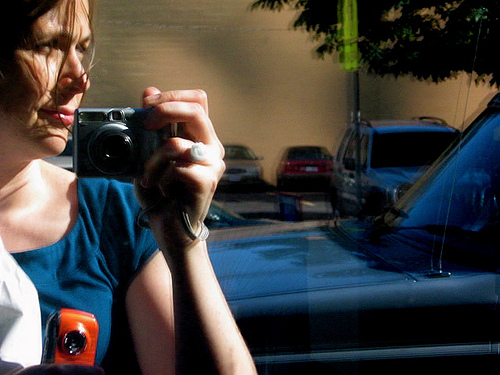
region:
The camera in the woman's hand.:
[74, 109, 189, 184]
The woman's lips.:
[38, 106, 71, 126]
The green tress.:
[260, 3, 498, 95]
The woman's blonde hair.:
[4, 0, 45, 137]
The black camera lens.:
[101, 136, 138, 162]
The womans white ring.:
[186, 143, 208, 163]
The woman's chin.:
[27, 129, 69, 160]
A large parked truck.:
[346, 115, 456, 228]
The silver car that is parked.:
[213, 137, 263, 188]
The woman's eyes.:
[37, 33, 94, 60]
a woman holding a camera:
[32, 61, 269, 314]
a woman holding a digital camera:
[36, 48, 342, 310]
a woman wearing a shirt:
[12, 16, 236, 333]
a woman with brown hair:
[12, 22, 267, 374]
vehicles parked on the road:
[237, 106, 479, 211]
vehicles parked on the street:
[198, 105, 418, 212]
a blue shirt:
[68, 249, 105, 297]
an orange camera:
[53, 313, 98, 366]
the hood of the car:
[244, 234, 313, 304]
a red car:
[279, 149, 331, 182]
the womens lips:
[50, 104, 71, 122]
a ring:
[185, 144, 212, 162]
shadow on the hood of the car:
[265, 234, 330, 269]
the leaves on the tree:
[406, 39, 453, 70]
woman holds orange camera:
[47, 313, 96, 363]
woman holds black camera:
[68, 107, 168, 175]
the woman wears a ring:
[188, 138, 205, 163]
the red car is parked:
[282, 146, 330, 185]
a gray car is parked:
[222, 145, 265, 188]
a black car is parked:
[335, 117, 455, 222]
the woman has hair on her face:
[1, 1, 94, 156]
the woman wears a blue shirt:
[0, 164, 163, 371]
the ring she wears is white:
[188, 142, 205, 162]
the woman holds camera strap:
[142, 202, 204, 242]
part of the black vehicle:
[450, 313, 495, 358]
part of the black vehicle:
[410, 317, 434, 373]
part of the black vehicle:
[364, 318, 382, 371]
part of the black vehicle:
[333, 320, 350, 371]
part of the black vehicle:
[286, 326, 311, 370]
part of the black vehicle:
[250, 277, 296, 317]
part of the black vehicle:
[316, 251, 348, 298]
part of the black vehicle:
[266, 240, 296, 270]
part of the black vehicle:
[407, 275, 419, 295]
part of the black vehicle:
[463, 273, 497, 310]